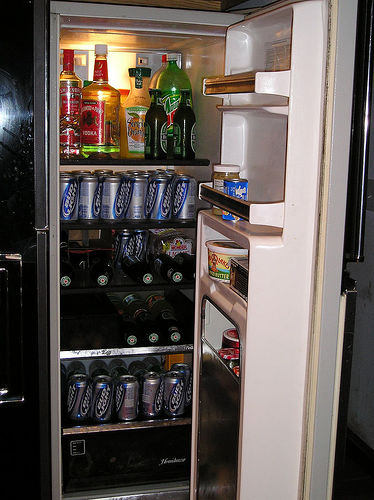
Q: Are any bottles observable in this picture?
A: Yes, there is a bottle.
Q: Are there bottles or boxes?
A: Yes, there is a bottle.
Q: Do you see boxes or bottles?
A: Yes, there is a bottle.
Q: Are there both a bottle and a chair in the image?
A: No, there is a bottle but no chairs.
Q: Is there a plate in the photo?
A: No, there are no plates.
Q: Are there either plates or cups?
A: No, there are no plates or cups.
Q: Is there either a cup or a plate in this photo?
A: No, there are no plates or cups.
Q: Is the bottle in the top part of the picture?
A: Yes, the bottle is in the top of the image.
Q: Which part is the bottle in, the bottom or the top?
A: The bottle is in the top of the image.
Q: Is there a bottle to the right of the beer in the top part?
A: Yes, there is a bottle to the right of the beer.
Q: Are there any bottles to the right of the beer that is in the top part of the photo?
A: Yes, there is a bottle to the right of the beer.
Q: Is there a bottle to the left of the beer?
A: No, the bottle is to the right of the beer.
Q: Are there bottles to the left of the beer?
A: No, the bottle is to the right of the beer.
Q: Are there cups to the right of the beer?
A: No, there is a bottle to the right of the beer.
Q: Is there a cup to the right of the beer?
A: No, there is a bottle to the right of the beer.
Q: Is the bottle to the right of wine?
A: No, the bottle is to the right of the beer.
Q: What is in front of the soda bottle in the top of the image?
A: The bottle is in front of the soda bottle.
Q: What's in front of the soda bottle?
A: The bottle is in front of the soda bottle.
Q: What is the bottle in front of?
A: The bottle is in front of the soda bottle.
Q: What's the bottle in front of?
A: The bottle is in front of the soda bottle.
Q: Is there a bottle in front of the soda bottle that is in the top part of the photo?
A: Yes, there is a bottle in front of the soda bottle.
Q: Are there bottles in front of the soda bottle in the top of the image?
A: Yes, there is a bottle in front of the soda bottle.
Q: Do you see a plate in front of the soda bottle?
A: No, there is a bottle in front of the soda bottle.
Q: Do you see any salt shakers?
A: No, there are no salt shakers.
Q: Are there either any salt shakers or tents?
A: No, there are no salt shakers or tents.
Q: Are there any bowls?
A: No, there are no bowls.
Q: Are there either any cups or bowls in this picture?
A: No, there are no bowls or cups.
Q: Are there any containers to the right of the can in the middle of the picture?
A: Yes, there is a container to the right of the can.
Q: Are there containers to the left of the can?
A: No, the container is to the right of the can.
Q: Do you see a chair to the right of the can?
A: No, there is a container to the right of the can.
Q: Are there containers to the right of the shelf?
A: Yes, there is a container to the right of the shelf.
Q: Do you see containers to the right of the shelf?
A: Yes, there is a container to the right of the shelf.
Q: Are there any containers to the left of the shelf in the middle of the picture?
A: No, the container is to the right of the shelf.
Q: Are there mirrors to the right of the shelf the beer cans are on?
A: No, there is a container to the right of the shelf.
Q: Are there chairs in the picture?
A: No, there are no chairs.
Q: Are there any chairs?
A: No, there are no chairs.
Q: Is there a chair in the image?
A: No, there are no chairs.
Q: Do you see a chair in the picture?
A: No, there are no chairs.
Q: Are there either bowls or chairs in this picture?
A: No, there are no chairs or bowls.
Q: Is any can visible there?
A: Yes, there is a can.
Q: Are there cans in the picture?
A: Yes, there is a can.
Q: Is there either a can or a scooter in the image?
A: Yes, there is a can.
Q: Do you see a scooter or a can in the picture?
A: Yes, there is a can.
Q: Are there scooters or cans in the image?
A: Yes, there is a can.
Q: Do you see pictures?
A: No, there are no pictures.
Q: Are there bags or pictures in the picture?
A: No, there are no pictures or bags.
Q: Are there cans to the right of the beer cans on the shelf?
A: Yes, there is a can to the right of the beer cans.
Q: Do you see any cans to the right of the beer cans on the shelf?
A: Yes, there is a can to the right of the beer cans.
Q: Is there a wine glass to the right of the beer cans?
A: No, there is a can to the right of the beer cans.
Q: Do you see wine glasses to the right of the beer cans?
A: No, there is a can to the right of the beer cans.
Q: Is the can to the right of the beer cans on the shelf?
A: Yes, the can is to the right of the beer cans.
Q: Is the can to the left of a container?
A: Yes, the can is to the left of a container.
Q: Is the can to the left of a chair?
A: No, the can is to the left of a container.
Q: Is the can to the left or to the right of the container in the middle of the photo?
A: The can is to the left of the container.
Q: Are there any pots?
A: No, there are no pots.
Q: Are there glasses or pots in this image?
A: No, there are no pots or glasses.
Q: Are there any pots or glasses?
A: No, there are no pots or glasses.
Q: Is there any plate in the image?
A: No, there are no plates.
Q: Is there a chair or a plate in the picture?
A: No, there are no plates or chairs.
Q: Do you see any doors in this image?
A: Yes, there is a door.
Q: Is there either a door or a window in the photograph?
A: Yes, there is a door.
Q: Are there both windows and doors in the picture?
A: No, there is a door but no windows.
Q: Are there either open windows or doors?
A: Yes, there is an open door.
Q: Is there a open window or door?
A: Yes, there is an open door.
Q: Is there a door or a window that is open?
A: Yes, the door is open.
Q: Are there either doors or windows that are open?
A: Yes, the door is open.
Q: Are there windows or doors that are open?
A: Yes, the door is open.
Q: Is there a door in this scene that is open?
A: Yes, there is an open door.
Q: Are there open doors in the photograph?
A: Yes, there is an open door.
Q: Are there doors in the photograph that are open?
A: Yes, there is a door that is open.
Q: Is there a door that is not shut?
A: Yes, there is a open door.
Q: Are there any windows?
A: No, there are no windows.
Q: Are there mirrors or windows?
A: No, there are no windows or mirrors.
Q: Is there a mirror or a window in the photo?
A: No, there are no windows or mirrors.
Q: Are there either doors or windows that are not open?
A: No, there is a door but it is open.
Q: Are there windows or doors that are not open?
A: No, there is a door but it is open.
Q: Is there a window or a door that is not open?
A: No, there is a door but it is open.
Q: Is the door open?
A: Yes, the door is open.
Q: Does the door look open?
A: Yes, the door is open.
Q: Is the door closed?
A: No, the door is open.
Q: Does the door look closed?
A: No, the door is open.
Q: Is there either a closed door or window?
A: No, there is a door but it is open.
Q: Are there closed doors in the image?
A: No, there is a door but it is open.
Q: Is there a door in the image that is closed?
A: No, there is a door but it is open.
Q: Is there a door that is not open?
A: No, there is a door but it is open.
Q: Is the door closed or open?
A: The door is open.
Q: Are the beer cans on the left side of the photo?
A: Yes, the beer cans are on the left of the image.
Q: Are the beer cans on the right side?
A: No, the beer cans are on the left of the image.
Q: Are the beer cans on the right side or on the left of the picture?
A: The beer cans are on the left of the image.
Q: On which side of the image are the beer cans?
A: The beer cans are on the left of the image.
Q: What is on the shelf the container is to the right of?
A: The beer cans are on the shelf.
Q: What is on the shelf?
A: The beer cans are on the shelf.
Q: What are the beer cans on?
A: The beer cans are on the shelf.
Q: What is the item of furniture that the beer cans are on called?
A: The piece of furniture is a shelf.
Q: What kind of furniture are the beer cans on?
A: The beer cans are on the shelf.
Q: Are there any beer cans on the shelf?
A: Yes, there are beer cans on the shelf.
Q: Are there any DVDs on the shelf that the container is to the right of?
A: No, there are beer cans on the shelf.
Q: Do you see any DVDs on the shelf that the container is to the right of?
A: No, there are beer cans on the shelf.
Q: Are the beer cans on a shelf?
A: Yes, the beer cans are on a shelf.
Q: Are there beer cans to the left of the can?
A: Yes, there are beer cans to the left of the can.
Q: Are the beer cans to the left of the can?
A: Yes, the beer cans are to the left of the can.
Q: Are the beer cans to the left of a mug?
A: No, the beer cans are to the left of the can.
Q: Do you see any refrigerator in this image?
A: Yes, there is a refrigerator.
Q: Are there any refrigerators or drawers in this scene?
A: Yes, there is a refrigerator.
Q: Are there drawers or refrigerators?
A: Yes, there is a refrigerator.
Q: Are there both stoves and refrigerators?
A: No, there is a refrigerator but no stoves.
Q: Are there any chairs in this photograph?
A: No, there are no chairs.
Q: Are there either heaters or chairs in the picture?
A: No, there are no chairs or heaters.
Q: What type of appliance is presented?
A: The appliance is a refrigerator.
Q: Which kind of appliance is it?
A: The appliance is a refrigerator.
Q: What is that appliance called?
A: This is a refrigerator.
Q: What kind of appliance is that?
A: This is a refrigerator.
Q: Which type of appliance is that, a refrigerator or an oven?
A: This is a refrigerator.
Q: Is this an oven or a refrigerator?
A: This is a refrigerator.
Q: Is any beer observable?
A: Yes, there is beer.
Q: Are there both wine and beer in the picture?
A: No, there is beer but no wine.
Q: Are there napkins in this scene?
A: No, there are no napkins.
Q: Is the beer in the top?
A: Yes, the beer is in the top of the image.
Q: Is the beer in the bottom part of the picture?
A: No, the beer is in the top of the image.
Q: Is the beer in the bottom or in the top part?
A: The beer is in the top of the image.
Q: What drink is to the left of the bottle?
A: The drink is beer.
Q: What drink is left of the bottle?
A: The drink is beer.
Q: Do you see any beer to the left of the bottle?
A: Yes, there is beer to the left of the bottle.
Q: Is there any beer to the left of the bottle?
A: Yes, there is beer to the left of the bottle.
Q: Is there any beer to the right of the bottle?
A: No, the beer is to the left of the bottle.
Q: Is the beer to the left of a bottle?
A: Yes, the beer is to the left of a bottle.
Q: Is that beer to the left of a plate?
A: No, the beer is to the left of a bottle.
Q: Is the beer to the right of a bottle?
A: No, the beer is to the left of a bottle.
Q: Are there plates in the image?
A: No, there are no plates.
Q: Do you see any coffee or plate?
A: No, there are no plates or coffee.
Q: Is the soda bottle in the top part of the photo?
A: Yes, the soda bottle is in the top of the image.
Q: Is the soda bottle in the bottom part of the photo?
A: No, the soda bottle is in the top of the image.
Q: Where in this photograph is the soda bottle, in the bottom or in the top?
A: The soda bottle is in the top of the image.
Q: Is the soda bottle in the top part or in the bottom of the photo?
A: The soda bottle is in the top of the image.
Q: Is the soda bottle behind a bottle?
A: Yes, the soda bottle is behind a bottle.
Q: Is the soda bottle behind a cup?
A: No, the soda bottle is behind a bottle.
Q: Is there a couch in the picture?
A: No, there are no couches.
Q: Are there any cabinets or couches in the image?
A: No, there are no couches or cabinets.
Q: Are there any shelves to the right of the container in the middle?
A: No, the shelf is to the left of the container.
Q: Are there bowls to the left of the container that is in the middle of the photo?
A: No, there is a shelf to the left of the container.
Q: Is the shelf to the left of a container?
A: Yes, the shelf is to the left of a container.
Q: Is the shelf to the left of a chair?
A: No, the shelf is to the left of a container.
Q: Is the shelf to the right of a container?
A: No, the shelf is to the left of a container.